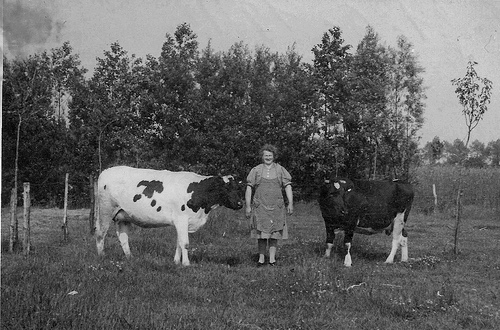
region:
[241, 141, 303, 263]
woman standing in field with cows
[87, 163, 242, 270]
black and white cow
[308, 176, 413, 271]
black and white cow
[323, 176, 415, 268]
black and white cow standing by woman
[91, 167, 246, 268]
black and white cow standing by woman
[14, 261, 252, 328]
grass in black and white photo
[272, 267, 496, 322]
grass in black and white photo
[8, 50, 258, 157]
trees in black and white photo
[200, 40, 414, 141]
trees in black and white photo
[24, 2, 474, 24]
sky in black and white photo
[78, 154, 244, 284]
a white cow with black spots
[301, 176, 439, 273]
a black cow with white spots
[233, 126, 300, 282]
a middle aged woman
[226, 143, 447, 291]
a woman with a cow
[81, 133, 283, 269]
a woman with a cow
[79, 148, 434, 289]
a woman with two cows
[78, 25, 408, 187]
tall trees behind a woman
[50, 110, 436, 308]
a woman and cows on grass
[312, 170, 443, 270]
a cow with white legs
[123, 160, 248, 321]
a cow with a black head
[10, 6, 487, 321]
an old picture of a farmer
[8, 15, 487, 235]
lots of trees on the farm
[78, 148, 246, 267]
a white cow in this photo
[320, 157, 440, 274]
a black cown on the grass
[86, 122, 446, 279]
the lady standing between her cows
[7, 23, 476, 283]
this picture is black and white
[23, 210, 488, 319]
there is a lot of grass on the ground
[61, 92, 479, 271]
this photo could have been taken during the 1920's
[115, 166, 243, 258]
this cow has spots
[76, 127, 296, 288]
this lady has on a milk maids outfit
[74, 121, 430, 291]
A woman standing between two cows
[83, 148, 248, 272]
The cow is white with black spots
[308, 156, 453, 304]
The cow is black with white areas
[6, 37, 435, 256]
A row of trees stand behind the woman and cows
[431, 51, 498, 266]
A small new tree by the cow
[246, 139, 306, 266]
The woman wears a dress and apron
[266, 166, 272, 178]
Buttons on the woman's dress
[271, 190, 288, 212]
Pocket on front of apron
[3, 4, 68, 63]
A gray cloud in the sky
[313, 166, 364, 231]
Cows head is black with little white spot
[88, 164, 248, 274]
white and black cow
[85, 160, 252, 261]
big white and black cow in a field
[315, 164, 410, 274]
small cow ina field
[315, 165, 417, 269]
small black cow with white legs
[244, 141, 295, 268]
woman in dress standing between cows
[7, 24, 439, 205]
a bunch of trees in the back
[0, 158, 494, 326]
field with short grass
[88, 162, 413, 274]
two cows standing in a field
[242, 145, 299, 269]
blonde fat woman in a dress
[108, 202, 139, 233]
udders of the white and black cow in the left